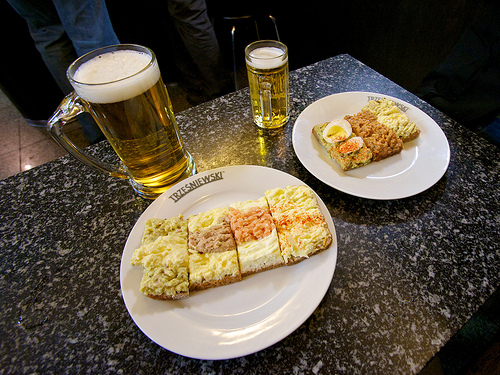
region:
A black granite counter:
[1, 51, 499, 367]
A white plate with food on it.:
[118, 164, 336, 359]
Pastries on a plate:
[131, 179, 331, 298]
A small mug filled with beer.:
[245, 40, 287, 129]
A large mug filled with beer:
[45, 42, 196, 195]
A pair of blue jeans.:
[56, 1, 122, 56]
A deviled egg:
[321, 116, 351, 141]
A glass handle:
[44, 91, 128, 182]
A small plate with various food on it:
[292, 89, 455, 201]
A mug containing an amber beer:
[48, 40, 200, 196]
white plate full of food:
[107, 163, 338, 365]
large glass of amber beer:
[50, 45, 197, 195]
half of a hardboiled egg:
[322, 115, 353, 142]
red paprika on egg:
[335, 137, 366, 162]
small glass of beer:
[238, 34, 295, 131]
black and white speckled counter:
[7, 190, 92, 285]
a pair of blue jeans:
[25, 0, 113, 47]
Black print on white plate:
[167, 168, 237, 204]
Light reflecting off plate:
[200, 318, 303, 346]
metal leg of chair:
[218, 19, 242, 82]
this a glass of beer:
[43, 41, 198, 194]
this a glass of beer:
[227, 27, 287, 128]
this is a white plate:
[120, 155, 333, 370]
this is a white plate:
[290, 86, 451, 201]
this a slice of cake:
[267, 188, 332, 260]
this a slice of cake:
[217, 190, 282, 270]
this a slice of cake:
[178, 208, 245, 293]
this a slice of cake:
[140, 220, 183, 300]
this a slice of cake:
[366, 90, 422, 151]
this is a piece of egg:
[318, 115, 355, 149]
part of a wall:
[199, 90, 242, 135]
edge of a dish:
[263, 322, 293, 362]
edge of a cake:
[148, 278, 190, 320]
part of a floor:
[348, 235, 398, 310]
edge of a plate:
[264, 295, 301, 339]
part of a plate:
[266, 305, 293, 337]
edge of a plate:
[203, 273, 248, 335]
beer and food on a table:
[29, 22, 469, 367]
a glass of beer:
[235, 30, 298, 131]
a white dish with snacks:
[289, 77, 458, 214]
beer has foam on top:
[234, 34, 298, 137]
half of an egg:
[317, 109, 357, 149]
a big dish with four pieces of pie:
[110, 156, 343, 367]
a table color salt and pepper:
[11, 53, 498, 369]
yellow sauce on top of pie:
[129, 206, 191, 303]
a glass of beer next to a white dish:
[31, 36, 204, 203]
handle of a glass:
[46, 98, 135, 190]